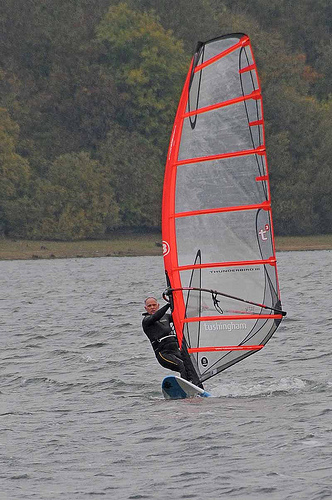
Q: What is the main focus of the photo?
A: A man on a surf board.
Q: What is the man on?
A: A surf board with a sail.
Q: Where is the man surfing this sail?
A: A body of water.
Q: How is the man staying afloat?
A: Surfboard.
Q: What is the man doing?
A: Windsurfing.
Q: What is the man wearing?
A: Wetsuit.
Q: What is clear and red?
A: Sail.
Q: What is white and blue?
A: Surfboard.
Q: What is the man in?
A: Water.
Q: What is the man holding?
A: Bar.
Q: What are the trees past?
A: Shore.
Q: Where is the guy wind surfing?
A: In a lake.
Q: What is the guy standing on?
A: A surf board.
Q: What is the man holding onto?
A: The wind sail.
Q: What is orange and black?
A: The sail.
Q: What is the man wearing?
A: A black body suit.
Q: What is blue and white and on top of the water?
A: The surbaord.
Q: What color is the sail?
A: Red.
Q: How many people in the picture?
A: One.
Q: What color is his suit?
A: Black.